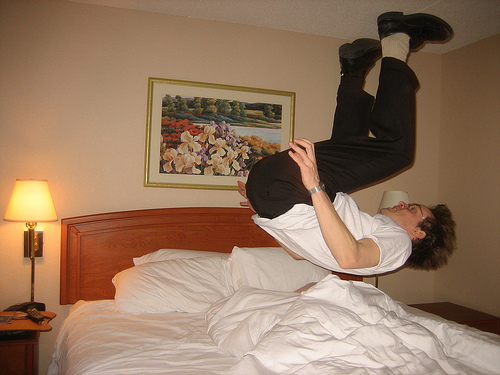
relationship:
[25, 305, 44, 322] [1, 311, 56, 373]
remote control on table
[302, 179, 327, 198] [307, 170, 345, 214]
silver watch on wrist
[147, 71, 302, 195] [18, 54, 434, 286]
picture on wall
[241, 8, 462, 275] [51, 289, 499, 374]
man jumping on bed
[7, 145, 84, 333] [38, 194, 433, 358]
lamp by bed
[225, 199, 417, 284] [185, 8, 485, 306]
shirt on man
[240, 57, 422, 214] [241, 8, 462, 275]
pants on man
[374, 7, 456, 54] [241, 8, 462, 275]
shoe on man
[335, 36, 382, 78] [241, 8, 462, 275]
shoe on man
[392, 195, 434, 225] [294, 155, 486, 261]
eyeglasses on man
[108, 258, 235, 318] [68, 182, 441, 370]
pillow on bed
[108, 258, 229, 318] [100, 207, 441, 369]
pillow on bed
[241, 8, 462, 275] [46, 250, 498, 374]
man flip off bed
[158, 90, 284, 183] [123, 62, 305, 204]
painting in frame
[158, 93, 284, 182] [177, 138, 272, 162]
painting of flowers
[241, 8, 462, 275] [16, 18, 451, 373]
man in hotel room